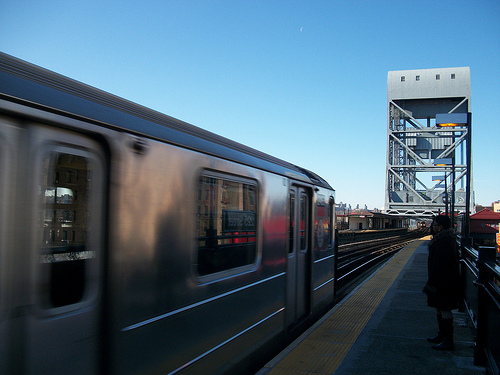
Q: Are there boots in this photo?
A: Yes, there are boots.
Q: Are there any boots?
A: Yes, there are boots.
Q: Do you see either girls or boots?
A: Yes, there are boots.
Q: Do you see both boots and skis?
A: No, there are boots but no skis.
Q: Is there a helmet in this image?
A: No, there are no helmets.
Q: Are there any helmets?
A: No, there are no helmets.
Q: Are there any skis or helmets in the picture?
A: No, there are no helmets or skis.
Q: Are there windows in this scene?
A: Yes, there is a window.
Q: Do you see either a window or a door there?
A: Yes, there is a window.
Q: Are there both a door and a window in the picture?
A: Yes, there are both a window and a door.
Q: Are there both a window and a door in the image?
A: Yes, there are both a window and a door.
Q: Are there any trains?
A: Yes, there is a train.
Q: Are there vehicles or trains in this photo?
A: Yes, there is a train.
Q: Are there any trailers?
A: No, there are no trailers.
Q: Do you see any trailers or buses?
A: No, there are no trailers or buses.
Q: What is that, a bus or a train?
A: That is a train.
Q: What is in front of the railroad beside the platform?
A: The train is in front of the railroad.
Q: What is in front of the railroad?
A: The train is in front of the railroad.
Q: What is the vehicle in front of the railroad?
A: The vehicle is a train.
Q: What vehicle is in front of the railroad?
A: The vehicle is a train.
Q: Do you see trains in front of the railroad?
A: Yes, there is a train in front of the railroad.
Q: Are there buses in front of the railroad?
A: No, there is a train in front of the railroad.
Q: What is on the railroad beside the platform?
A: The train is on the railroad.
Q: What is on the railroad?
A: The train is on the railroad.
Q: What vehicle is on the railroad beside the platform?
A: The vehicle is a train.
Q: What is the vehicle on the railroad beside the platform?
A: The vehicle is a train.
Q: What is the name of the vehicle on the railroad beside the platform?
A: The vehicle is a train.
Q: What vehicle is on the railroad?
A: The vehicle is a train.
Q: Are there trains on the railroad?
A: Yes, there is a train on the railroad.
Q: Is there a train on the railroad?
A: Yes, there is a train on the railroad.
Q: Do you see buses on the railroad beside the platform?
A: No, there is a train on the railroad.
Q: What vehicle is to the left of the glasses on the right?
A: The vehicle is a train.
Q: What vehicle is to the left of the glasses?
A: The vehicle is a train.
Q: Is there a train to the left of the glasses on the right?
A: Yes, there is a train to the left of the glasses.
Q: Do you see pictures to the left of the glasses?
A: No, there is a train to the left of the glasses.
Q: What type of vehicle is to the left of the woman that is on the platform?
A: The vehicle is a train.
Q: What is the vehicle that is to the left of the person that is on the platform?
A: The vehicle is a train.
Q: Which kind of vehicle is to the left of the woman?
A: The vehicle is a train.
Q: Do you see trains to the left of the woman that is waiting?
A: Yes, there is a train to the left of the woman.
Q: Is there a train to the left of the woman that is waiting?
A: Yes, there is a train to the left of the woman.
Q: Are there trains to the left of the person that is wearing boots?
A: Yes, there is a train to the left of the woman.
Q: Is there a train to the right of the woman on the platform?
A: No, the train is to the left of the woman.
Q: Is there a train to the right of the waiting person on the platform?
A: No, the train is to the left of the woman.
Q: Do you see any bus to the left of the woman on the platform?
A: No, there is a train to the left of the woman.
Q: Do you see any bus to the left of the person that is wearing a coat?
A: No, there is a train to the left of the woman.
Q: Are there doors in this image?
A: Yes, there is a door.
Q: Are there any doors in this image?
A: Yes, there is a door.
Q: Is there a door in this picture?
A: Yes, there is a door.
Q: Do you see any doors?
A: Yes, there is a door.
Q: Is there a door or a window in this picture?
A: Yes, there is a door.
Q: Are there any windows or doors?
A: Yes, there is a door.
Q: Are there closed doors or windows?
A: Yes, there is a closed door.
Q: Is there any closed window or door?
A: Yes, there is a closed door.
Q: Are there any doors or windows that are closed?
A: Yes, the door is closed.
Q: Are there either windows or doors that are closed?
A: Yes, the door is closed.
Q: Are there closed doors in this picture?
A: Yes, there is a closed door.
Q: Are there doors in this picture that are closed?
A: Yes, there is a door that is closed.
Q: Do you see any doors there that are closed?
A: Yes, there is a door that is closed.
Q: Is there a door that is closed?
A: Yes, there is a door that is closed.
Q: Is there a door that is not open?
A: Yes, there is an closed door.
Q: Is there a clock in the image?
A: No, there are no clocks.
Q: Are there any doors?
A: Yes, there is a door.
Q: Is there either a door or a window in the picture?
A: Yes, there is a door.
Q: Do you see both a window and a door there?
A: Yes, there are both a door and a window.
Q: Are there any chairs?
A: No, there are no chairs.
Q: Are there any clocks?
A: No, there are no clocks.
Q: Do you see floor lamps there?
A: No, there are no floor lamps.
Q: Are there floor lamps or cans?
A: No, there are no floor lamps or cans.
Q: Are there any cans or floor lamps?
A: No, there are no floor lamps or cans.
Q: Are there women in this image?
A: Yes, there is a woman.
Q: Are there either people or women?
A: Yes, there is a woman.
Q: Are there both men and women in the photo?
A: No, there is a woman but no men.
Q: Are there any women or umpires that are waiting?
A: Yes, the woman is waiting.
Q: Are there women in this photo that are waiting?
A: Yes, there is a woman that is waiting.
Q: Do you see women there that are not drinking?
A: Yes, there is a woman that is waiting .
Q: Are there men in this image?
A: No, there are no men.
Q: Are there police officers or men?
A: No, there are no men or police officers.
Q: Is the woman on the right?
A: Yes, the woman is on the right of the image.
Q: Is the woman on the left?
A: No, the woman is on the right of the image.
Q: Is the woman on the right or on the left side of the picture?
A: The woman is on the right of the image.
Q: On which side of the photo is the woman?
A: The woman is on the right of the image.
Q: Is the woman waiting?
A: Yes, the woman is waiting.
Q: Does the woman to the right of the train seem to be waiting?
A: Yes, the woman is waiting.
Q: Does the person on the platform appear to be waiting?
A: Yes, the woman is waiting.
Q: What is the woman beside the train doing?
A: The woman is waiting.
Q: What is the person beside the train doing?
A: The woman is waiting.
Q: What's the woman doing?
A: The woman is waiting.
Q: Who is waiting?
A: The woman is waiting.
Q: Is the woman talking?
A: No, the woman is waiting.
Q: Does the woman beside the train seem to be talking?
A: No, the woman is waiting.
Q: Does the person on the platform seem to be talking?
A: No, the woman is waiting.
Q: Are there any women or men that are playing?
A: No, there is a woman but she is waiting.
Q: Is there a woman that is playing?
A: No, there is a woman but she is waiting.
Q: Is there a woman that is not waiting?
A: No, there is a woman but she is waiting.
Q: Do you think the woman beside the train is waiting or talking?
A: The woman is waiting.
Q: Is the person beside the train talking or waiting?
A: The woman is waiting.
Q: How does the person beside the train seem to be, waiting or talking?
A: The woman is waiting.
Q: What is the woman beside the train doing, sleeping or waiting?
A: The woman is waiting.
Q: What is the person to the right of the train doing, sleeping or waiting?
A: The woman is waiting.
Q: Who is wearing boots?
A: The woman is wearing boots.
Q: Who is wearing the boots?
A: The woman is wearing boots.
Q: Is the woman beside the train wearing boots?
A: Yes, the woman is wearing boots.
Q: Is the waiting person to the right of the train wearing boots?
A: Yes, the woman is wearing boots.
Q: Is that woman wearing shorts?
A: No, the woman is wearing boots.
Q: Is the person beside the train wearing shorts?
A: No, the woman is wearing boots.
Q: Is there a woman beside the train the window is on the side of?
A: Yes, there is a woman beside the train.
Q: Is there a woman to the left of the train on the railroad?
A: No, the woman is to the right of the train.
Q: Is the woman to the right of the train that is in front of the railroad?
A: Yes, the woman is to the right of the train.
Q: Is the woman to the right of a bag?
A: No, the woman is to the right of the train.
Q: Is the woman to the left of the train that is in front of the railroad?
A: No, the woman is to the right of the train.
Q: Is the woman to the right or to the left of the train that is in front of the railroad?
A: The woman is to the right of the train.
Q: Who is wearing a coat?
A: The woman is wearing a coat.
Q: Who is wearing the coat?
A: The woman is wearing a coat.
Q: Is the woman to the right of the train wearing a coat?
A: Yes, the woman is wearing a coat.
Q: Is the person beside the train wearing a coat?
A: Yes, the woman is wearing a coat.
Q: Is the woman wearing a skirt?
A: No, the woman is wearing a coat.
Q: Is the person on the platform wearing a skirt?
A: No, the woman is wearing a coat.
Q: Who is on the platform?
A: The woman is on the platform.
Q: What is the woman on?
A: The woman is on the platform.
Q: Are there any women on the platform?
A: Yes, there is a woman on the platform.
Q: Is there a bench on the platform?
A: No, there is a woman on the platform.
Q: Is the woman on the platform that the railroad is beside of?
A: Yes, the woman is on the platform.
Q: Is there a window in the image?
A: Yes, there is a window.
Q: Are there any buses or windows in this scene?
A: Yes, there is a window.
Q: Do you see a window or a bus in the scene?
A: Yes, there is a window.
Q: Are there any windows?
A: Yes, there is a window.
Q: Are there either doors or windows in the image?
A: Yes, there is a window.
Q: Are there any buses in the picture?
A: No, there are no buses.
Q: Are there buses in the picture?
A: No, there are no buses.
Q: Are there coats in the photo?
A: Yes, there is a coat.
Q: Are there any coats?
A: Yes, there is a coat.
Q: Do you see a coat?
A: Yes, there is a coat.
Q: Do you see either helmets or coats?
A: Yes, there is a coat.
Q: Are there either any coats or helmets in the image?
A: Yes, there is a coat.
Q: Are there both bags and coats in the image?
A: No, there is a coat but no bags.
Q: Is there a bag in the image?
A: No, there are no bags.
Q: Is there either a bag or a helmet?
A: No, there are no bags or helmets.